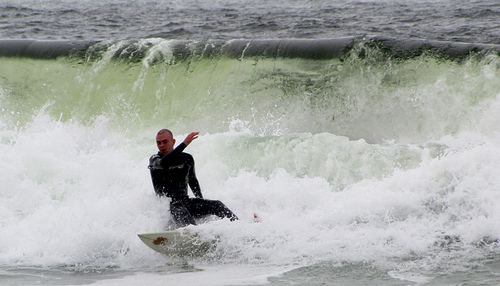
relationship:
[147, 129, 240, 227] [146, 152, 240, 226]
surfer has suit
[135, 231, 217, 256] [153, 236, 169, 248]
surfboard has logo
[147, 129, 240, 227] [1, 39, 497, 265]
surfer on wave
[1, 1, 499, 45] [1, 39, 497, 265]
water behind wave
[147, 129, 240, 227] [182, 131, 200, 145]
surfer has hand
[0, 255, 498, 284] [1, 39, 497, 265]
water in front of wave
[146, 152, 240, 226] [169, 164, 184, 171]
suit has logo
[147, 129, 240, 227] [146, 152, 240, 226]
surfer in suit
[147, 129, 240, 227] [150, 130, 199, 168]
surfer has arm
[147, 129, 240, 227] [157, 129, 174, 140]
surfer has hair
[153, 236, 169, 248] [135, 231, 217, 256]
logo on surfboard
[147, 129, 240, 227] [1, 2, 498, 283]
surfer in ocean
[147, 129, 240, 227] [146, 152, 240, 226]
surfer wearing suit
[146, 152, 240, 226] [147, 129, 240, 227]
suit on surfer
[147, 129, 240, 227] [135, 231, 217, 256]
surfer on surfboard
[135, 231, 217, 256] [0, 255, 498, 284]
surfboard in water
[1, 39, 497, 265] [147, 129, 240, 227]
wave behind surfer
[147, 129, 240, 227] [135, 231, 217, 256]
surfer standing on surfboard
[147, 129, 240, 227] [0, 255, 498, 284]
surfer on water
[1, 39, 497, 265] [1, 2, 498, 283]
wave on ocean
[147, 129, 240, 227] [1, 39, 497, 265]
surfer in wave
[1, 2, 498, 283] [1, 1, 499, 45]
ocean has water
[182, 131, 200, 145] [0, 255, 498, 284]
hand near water